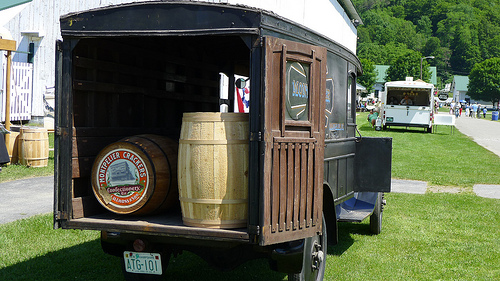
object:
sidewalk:
[449, 109, 500, 158]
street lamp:
[420, 55, 436, 82]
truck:
[374, 76, 434, 133]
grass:
[390, 131, 499, 186]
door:
[70, 34, 266, 230]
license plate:
[121, 251, 162, 275]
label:
[95, 149, 146, 208]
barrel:
[15, 128, 50, 169]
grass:
[0, 161, 51, 182]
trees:
[383, 52, 433, 83]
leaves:
[403, 63, 410, 66]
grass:
[331, 192, 499, 281]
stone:
[406, 178, 429, 195]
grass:
[0, 229, 98, 279]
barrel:
[176, 110, 252, 228]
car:
[51, 0, 392, 281]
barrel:
[90, 134, 177, 218]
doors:
[257, 37, 325, 248]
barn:
[0, 0, 363, 137]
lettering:
[115, 152, 121, 158]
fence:
[1, 59, 33, 123]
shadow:
[1, 236, 295, 281]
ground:
[0, 216, 96, 281]